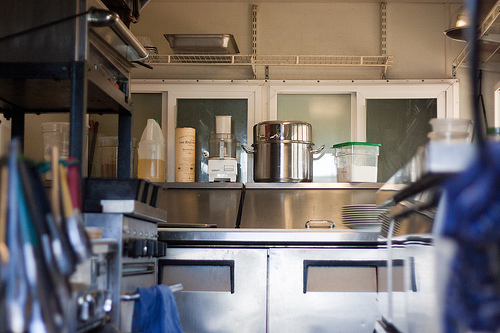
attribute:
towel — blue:
[132, 280, 188, 330]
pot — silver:
[233, 120, 325, 180]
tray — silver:
[161, 31, 241, 59]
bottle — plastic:
[137, 117, 168, 179]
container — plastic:
[335, 140, 378, 181]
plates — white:
[337, 203, 390, 229]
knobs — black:
[117, 236, 172, 260]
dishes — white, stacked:
[339, 190, 402, 241]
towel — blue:
[105, 271, 204, 331]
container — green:
[317, 126, 393, 201]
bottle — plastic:
[118, 108, 188, 203]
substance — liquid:
[128, 154, 173, 184]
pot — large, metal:
[228, 108, 330, 194]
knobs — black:
[118, 233, 176, 264]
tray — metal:
[154, 24, 248, 73]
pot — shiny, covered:
[239, 110, 331, 190]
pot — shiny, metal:
[229, 113, 329, 186]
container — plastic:
[319, 120, 400, 199]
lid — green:
[327, 134, 393, 153]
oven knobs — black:
[116, 232, 180, 272]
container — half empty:
[129, 111, 170, 197]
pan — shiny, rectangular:
[146, 19, 247, 70]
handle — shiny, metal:
[282, 208, 345, 233]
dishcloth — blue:
[108, 279, 200, 331]